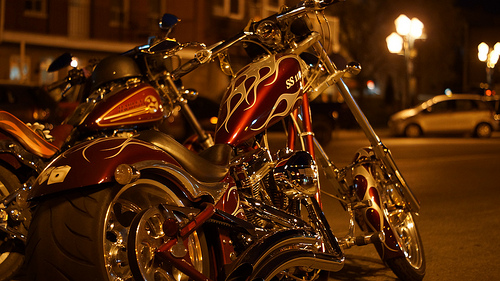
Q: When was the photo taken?
A: Night time.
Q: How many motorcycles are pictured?
A: Two.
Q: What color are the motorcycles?
A: Red and silver.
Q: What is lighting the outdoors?
A: Street lights.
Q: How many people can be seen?
A: None.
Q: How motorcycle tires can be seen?
A: Three.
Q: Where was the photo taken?
A: In a parking space.